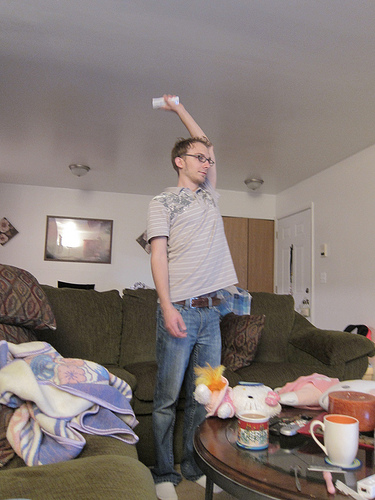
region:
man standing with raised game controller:
[142, 92, 237, 498]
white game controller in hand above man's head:
[151, 93, 182, 112]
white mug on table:
[309, 411, 362, 468]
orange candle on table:
[325, 388, 374, 433]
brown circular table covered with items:
[189, 388, 373, 498]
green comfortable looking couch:
[30, 284, 374, 465]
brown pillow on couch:
[220, 315, 264, 374]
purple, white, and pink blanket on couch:
[0, 340, 140, 465]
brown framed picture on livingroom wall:
[42, 214, 115, 265]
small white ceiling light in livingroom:
[67, 163, 91, 177]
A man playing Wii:
[122, 64, 253, 499]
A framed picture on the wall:
[39, 210, 120, 271]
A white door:
[266, 188, 323, 363]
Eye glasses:
[174, 146, 224, 168]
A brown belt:
[161, 294, 229, 313]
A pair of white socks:
[144, 468, 236, 499]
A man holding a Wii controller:
[137, 78, 266, 304]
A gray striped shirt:
[138, 176, 264, 316]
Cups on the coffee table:
[216, 401, 370, 492]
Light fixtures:
[2, 141, 322, 220]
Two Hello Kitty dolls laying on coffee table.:
[205, 366, 373, 430]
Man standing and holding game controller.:
[137, 77, 235, 484]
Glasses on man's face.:
[170, 147, 226, 171]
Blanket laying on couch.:
[2, 340, 115, 485]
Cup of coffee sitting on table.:
[223, 401, 286, 457]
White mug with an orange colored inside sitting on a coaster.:
[308, 411, 368, 473]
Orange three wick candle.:
[323, 385, 373, 420]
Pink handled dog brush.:
[306, 462, 356, 497]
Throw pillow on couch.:
[212, 305, 273, 381]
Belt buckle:
[182, 295, 204, 309]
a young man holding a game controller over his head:
[106, 78, 243, 493]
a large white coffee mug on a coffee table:
[303, 404, 373, 475]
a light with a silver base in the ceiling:
[68, 155, 92, 180]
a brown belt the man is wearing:
[183, 291, 225, 308]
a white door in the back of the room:
[274, 208, 315, 337]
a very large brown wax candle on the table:
[325, 390, 373, 431]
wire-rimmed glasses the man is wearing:
[191, 153, 216, 170]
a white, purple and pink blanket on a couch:
[1, 333, 143, 468]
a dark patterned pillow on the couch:
[0, 256, 56, 334]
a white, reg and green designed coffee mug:
[233, 406, 268, 454]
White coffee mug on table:
[316, 396, 337, 438]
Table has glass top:
[214, 443, 259, 495]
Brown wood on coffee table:
[191, 413, 227, 473]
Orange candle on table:
[307, 370, 367, 430]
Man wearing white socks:
[143, 486, 207, 491]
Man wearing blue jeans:
[138, 371, 188, 431]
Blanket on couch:
[10, 354, 76, 478]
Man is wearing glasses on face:
[182, 143, 252, 193]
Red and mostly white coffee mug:
[236, 391, 267, 441]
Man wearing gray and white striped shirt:
[170, 243, 235, 290]